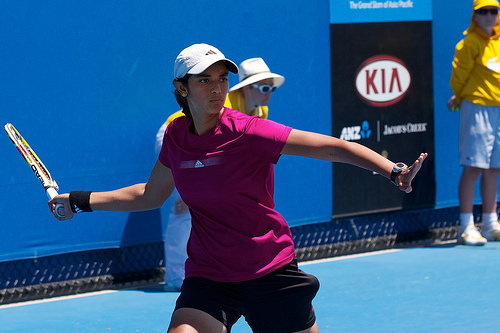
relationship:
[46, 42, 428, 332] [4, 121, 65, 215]
woman holding racket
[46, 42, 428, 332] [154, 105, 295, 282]
woman wearing shirt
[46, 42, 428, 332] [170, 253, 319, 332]
woman wearing shorts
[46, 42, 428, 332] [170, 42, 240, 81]
woman wearing cap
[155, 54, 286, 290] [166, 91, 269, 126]
man wearing shirt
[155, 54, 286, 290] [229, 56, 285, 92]
man wearing hat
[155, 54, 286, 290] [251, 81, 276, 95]
man wearing sunglasses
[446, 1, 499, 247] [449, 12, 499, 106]
man wearing sweatshirt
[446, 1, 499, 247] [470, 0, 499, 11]
man wearing cap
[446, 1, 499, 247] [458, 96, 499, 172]
man wearing shorts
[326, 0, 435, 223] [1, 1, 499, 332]
advertisement on wall of tennis court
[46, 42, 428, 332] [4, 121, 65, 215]
woman using racket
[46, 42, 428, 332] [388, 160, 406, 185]
woman wearing watch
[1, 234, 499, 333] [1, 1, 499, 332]
court inside of tennis court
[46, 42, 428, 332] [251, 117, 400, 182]
woman extending arm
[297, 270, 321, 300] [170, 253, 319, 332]
ball inside of shorts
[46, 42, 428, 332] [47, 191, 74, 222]
woman has right hand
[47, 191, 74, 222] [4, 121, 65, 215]
right hand holding racket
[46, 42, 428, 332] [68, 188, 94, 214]
woman wearing wristband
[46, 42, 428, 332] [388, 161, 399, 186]
woman has left wrist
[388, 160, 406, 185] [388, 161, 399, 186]
watch around left wrist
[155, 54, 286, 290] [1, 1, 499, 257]
man back to wall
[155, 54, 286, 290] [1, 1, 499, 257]
man standing close to wall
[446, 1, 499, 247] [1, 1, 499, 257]
man standing close to wall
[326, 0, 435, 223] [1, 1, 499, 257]
advertisement hanging on wall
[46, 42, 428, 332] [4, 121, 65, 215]
woman swinging racket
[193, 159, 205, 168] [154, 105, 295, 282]
triangle on front of shirt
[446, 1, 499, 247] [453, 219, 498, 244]
man wearing shoes